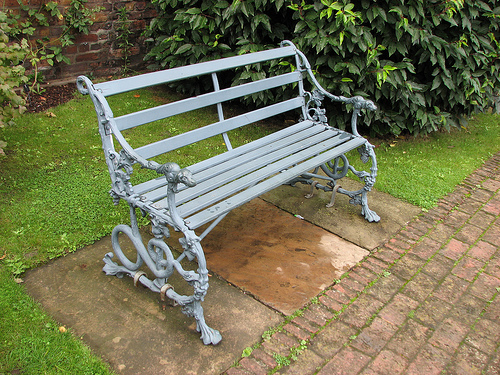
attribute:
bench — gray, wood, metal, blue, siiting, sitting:
[69, 38, 383, 346]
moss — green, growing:
[235, 202, 499, 362]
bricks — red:
[197, 152, 499, 374]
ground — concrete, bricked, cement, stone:
[23, 165, 446, 375]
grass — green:
[3, 86, 495, 372]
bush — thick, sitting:
[141, 4, 492, 129]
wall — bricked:
[5, 4, 153, 107]